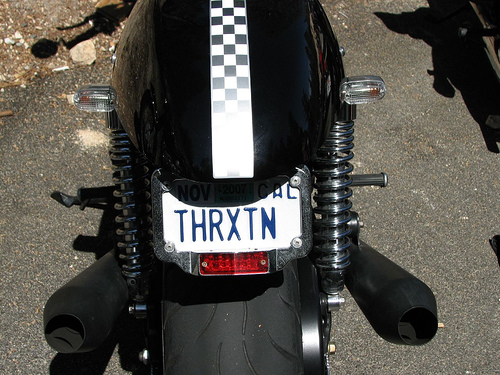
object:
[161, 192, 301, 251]
plate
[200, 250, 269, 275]
taillight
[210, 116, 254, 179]
white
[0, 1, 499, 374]
ground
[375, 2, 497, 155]
shadow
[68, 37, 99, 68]
rock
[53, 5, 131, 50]
handle bar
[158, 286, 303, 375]
tire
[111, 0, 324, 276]
back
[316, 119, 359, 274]
spring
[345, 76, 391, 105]
light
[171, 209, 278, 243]
letters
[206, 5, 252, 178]
design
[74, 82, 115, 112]
signal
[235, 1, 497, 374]
right turn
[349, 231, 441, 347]
muffler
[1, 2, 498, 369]
pavement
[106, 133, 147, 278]
coil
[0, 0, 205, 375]
left turn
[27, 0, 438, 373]
bike